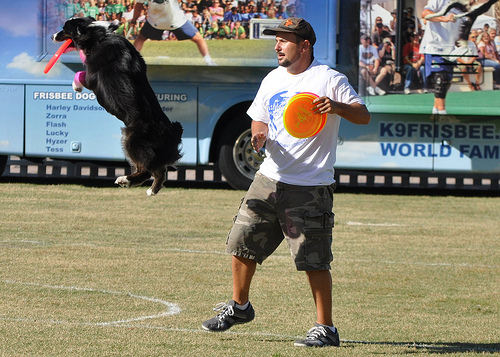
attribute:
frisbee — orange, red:
[284, 90, 326, 143]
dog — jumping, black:
[40, 17, 185, 202]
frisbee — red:
[41, 39, 75, 76]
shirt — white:
[248, 58, 361, 187]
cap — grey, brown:
[259, 20, 318, 43]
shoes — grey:
[199, 296, 338, 347]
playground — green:
[2, 185, 498, 357]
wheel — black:
[212, 105, 267, 190]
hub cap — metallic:
[233, 129, 267, 179]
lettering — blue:
[265, 92, 288, 132]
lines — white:
[19, 236, 183, 336]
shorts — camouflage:
[229, 170, 335, 268]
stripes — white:
[216, 310, 246, 326]